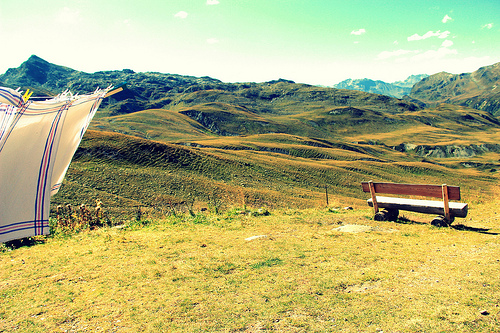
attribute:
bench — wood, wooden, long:
[361, 180, 467, 227]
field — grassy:
[0, 201, 499, 331]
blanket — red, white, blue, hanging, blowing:
[1, 86, 106, 245]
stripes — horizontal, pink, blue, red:
[1, 219, 51, 234]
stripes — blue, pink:
[1, 89, 24, 107]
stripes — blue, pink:
[21, 105, 68, 115]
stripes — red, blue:
[34, 99, 67, 232]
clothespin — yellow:
[22, 86, 35, 105]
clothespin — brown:
[99, 86, 123, 101]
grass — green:
[0, 209, 498, 331]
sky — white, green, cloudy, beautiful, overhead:
[1, 1, 497, 87]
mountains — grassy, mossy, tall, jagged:
[2, 53, 499, 111]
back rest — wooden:
[360, 180, 460, 199]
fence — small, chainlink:
[53, 201, 199, 231]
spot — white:
[329, 223, 372, 237]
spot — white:
[242, 234, 267, 242]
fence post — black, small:
[323, 184, 329, 205]